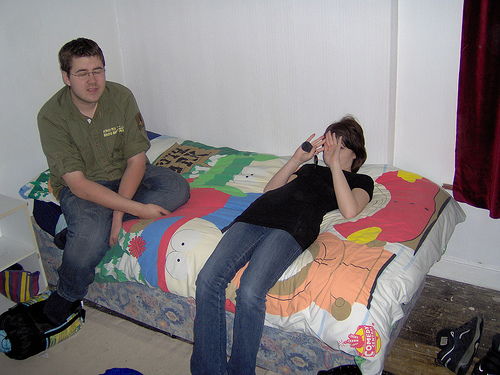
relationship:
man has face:
[38, 36, 191, 323] [73, 59, 105, 101]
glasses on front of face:
[67, 66, 106, 80] [73, 59, 105, 101]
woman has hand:
[188, 115, 376, 374] [293, 134, 325, 160]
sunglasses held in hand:
[302, 140, 319, 167] [293, 134, 325, 160]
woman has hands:
[188, 115, 376, 374] [293, 128, 344, 166]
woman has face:
[188, 115, 376, 374] [325, 133, 346, 166]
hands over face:
[293, 128, 344, 166] [325, 133, 346, 166]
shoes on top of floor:
[433, 312, 497, 374] [1, 272, 497, 373]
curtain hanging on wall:
[452, 0, 499, 219] [114, 0, 499, 293]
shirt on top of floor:
[98, 366, 148, 374] [1, 272, 497, 373]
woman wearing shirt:
[188, 115, 376, 374] [235, 162, 374, 250]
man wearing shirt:
[38, 36, 191, 323] [37, 80, 151, 196]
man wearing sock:
[38, 36, 191, 323] [53, 223, 70, 251]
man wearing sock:
[38, 36, 191, 323] [42, 291, 71, 323]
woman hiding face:
[188, 115, 376, 374] [325, 133, 346, 166]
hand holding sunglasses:
[293, 134, 325, 160] [302, 140, 319, 167]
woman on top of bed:
[188, 115, 376, 374] [19, 130, 466, 374]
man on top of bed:
[38, 36, 191, 323] [19, 130, 466, 374]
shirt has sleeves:
[37, 80, 151, 196] [37, 89, 152, 186]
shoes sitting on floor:
[433, 312, 497, 374] [1, 272, 497, 373]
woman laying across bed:
[188, 115, 376, 374] [19, 130, 466, 374]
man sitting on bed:
[38, 36, 191, 323] [19, 130, 466, 374]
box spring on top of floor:
[31, 216, 426, 374] [1, 272, 497, 373]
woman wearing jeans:
[188, 115, 376, 374] [189, 220, 304, 374]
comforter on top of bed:
[19, 129, 466, 359] [19, 130, 466, 374]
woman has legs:
[188, 115, 376, 374] [188, 221, 300, 374]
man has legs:
[38, 36, 191, 323] [56, 163, 192, 300]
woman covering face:
[188, 115, 376, 374] [325, 133, 346, 166]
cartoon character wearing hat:
[128, 215, 263, 312] [127, 215, 196, 294]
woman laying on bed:
[188, 115, 376, 374] [19, 130, 466, 374]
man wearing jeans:
[38, 36, 191, 323] [56, 163, 192, 302]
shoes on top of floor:
[433, 312, 485, 372] [1, 272, 497, 373]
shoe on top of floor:
[472, 333, 499, 373] [1, 272, 497, 373]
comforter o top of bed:
[19, 129, 466, 359] [19, 130, 466, 374]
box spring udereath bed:
[31, 216, 426, 374] [19, 130, 466, 374]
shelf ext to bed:
[0, 228, 35, 282] [19, 130, 466, 374]